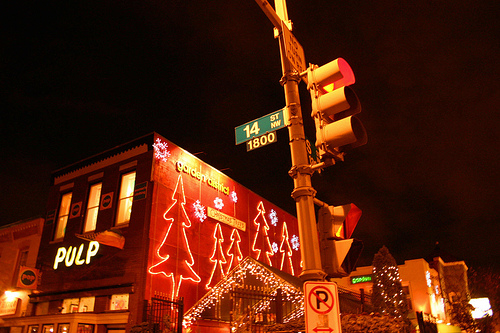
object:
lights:
[146, 173, 203, 314]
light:
[309, 85, 364, 119]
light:
[298, 55, 358, 92]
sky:
[0, 0, 499, 270]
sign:
[299, 279, 343, 332]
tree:
[203, 219, 228, 294]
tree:
[245, 200, 275, 271]